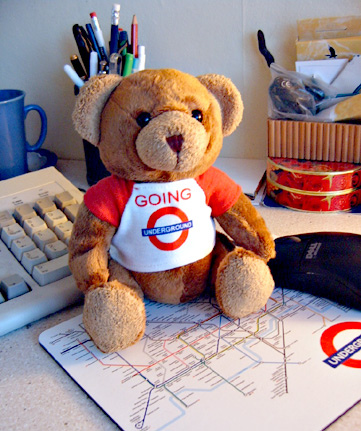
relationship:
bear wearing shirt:
[69, 68, 277, 355] [82, 165, 244, 273]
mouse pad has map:
[37, 283, 359, 430] [49, 283, 360, 431]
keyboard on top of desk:
[1, 166, 104, 339] [4, 158, 359, 430]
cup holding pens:
[72, 84, 110, 186] [63, 4, 147, 95]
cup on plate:
[1, 88, 48, 179] [27, 149, 59, 171]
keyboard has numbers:
[1, 166, 104, 339] [5, 210, 78, 263]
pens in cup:
[63, 4, 147, 95] [72, 84, 110, 186]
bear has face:
[69, 68, 277, 355] [98, 67, 225, 182]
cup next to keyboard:
[1, 88, 48, 179] [1, 166, 104, 339]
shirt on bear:
[82, 165, 244, 273] [69, 68, 277, 355]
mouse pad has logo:
[37, 283, 359, 430] [320, 320, 360, 370]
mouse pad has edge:
[37, 283, 359, 430] [33, 313, 112, 338]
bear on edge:
[69, 68, 277, 355] [33, 313, 112, 338]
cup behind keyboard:
[72, 84, 110, 186] [1, 166, 104, 339]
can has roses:
[265, 157, 361, 214] [265, 158, 359, 211]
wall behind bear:
[1, 2, 360, 157] [69, 68, 277, 355]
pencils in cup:
[84, 1, 139, 73] [72, 84, 110, 186]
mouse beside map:
[270, 231, 360, 310] [49, 283, 360, 431]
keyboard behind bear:
[1, 166, 104, 339] [69, 68, 277, 355]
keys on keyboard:
[0, 188, 83, 303] [1, 166, 104, 339]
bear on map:
[69, 68, 277, 355] [49, 283, 360, 431]